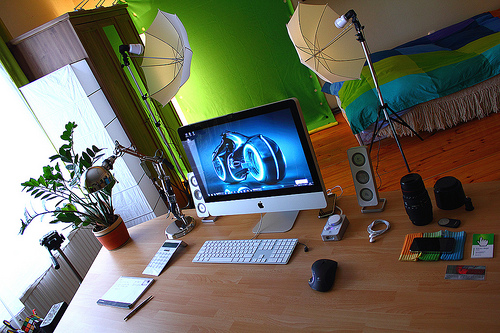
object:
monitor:
[176, 97, 327, 234]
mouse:
[302, 257, 338, 293]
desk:
[41, 177, 499, 332]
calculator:
[140, 238, 192, 276]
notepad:
[96, 274, 154, 309]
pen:
[122, 294, 155, 323]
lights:
[283, 3, 430, 177]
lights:
[113, 7, 194, 206]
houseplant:
[17, 121, 135, 252]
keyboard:
[190, 237, 297, 268]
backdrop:
[108, 1, 341, 156]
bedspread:
[317, 8, 500, 150]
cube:
[40, 300, 66, 329]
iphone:
[408, 237, 455, 253]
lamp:
[76, 133, 197, 241]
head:
[76, 164, 117, 194]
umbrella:
[283, 1, 374, 86]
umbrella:
[135, 9, 195, 107]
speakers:
[343, 141, 386, 214]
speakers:
[184, 168, 216, 223]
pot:
[90, 214, 134, 254]